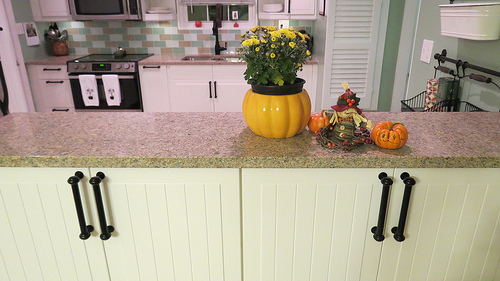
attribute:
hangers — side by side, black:
[400, 60, 499, 108]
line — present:
[451, 64, 462, 75]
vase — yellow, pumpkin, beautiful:
[240, 86, 313, 133]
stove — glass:
[72, 37, 149, 114]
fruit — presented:
[189, 20, 202, 30]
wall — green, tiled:
[31, 7, 296, 57]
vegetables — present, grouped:
[318, 89, 419, 143]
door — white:
[326, 3, 397, 123]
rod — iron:
[433, 50, 500, 79]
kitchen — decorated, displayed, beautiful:
[1, 2, 500, 248]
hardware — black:
[206, 80, 225, 106]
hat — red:
[332, 86, 362, 113]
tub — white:
[187, 48, 248, 71]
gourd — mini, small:
[374, 118, 407, 149]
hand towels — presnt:
[71, 74, 131, 109]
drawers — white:
[36, 62, 75, 119]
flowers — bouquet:
[238, 22, 312, 61]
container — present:
[44, 26, 72, 54]